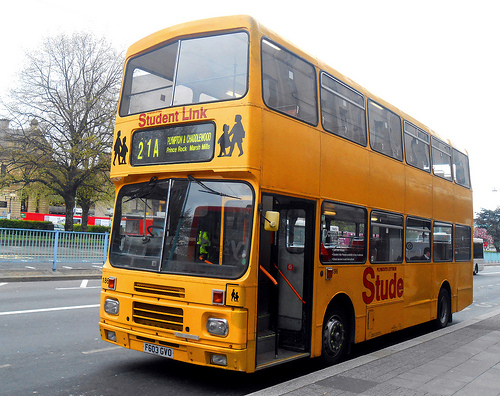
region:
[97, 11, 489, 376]
A yellow double-decker school bus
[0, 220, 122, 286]
A blue fence dividing two roads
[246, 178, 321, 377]
An open door on the bus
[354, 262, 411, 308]
Cut-off writing on the side of the bus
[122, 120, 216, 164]
The bus's route information sign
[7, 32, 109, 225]
Mostly leafless trees beside the road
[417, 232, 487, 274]
A white bus visible through/behind the school bus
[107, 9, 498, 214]
The top floor of the bus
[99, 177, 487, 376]
The bottom floor of the bus, with door.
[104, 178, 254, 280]
Front window with wipers coming from the top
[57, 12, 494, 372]
a yellow double decker bus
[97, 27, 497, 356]
a yellow passenger bus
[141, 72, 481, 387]
a bus with door open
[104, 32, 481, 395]
a buse with two levels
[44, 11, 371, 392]
a bus on the road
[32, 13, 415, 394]
a bus parked on the road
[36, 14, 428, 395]
a double decker bus on the road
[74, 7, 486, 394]
a double decker bus parked on the road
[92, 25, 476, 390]
a bus with windows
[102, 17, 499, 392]
a yellow bus with windows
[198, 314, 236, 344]
right light on bus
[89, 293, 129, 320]
left light on bus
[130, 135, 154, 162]
number twenty-one in yellow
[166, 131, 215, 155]
yellow lettering on bus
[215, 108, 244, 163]
printed man and woman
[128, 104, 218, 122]
words student link on bus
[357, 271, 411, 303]
large red lettering on bus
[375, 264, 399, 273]
small lettering on bus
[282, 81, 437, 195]
top row of bus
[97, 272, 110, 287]
small print numbers on bus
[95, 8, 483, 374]
yellow double decker bus on a street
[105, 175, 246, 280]
double decker bus windshield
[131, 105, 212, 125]
red text on yellow bus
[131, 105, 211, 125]
red print on a yellow bus reading Student link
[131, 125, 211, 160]
digital text on the front of the bus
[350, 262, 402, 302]
red print on the side of the bus reading Stude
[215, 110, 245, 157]
silhouette graphic on a yellow bus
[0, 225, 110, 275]
blue gate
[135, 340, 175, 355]
license plate on the front of a bus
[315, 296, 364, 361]
black bus wheel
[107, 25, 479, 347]
a double decker bus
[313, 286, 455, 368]
the wheels on the bus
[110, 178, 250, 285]
the front windshield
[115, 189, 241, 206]
the windshield wiper blades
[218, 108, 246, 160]
A picture of children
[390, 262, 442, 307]
spray paint on the side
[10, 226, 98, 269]
a blue fence on the sidewalk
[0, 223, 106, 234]
the handrail of the fence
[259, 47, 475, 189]
A row of windows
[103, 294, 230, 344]
the headlights on the bus